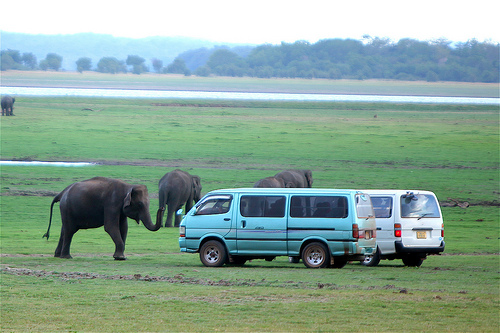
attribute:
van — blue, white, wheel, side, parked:
[153, 112, 454, 276]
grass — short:
[178, 289, 217, 316]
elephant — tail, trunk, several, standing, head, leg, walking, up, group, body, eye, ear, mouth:
[36, 163, 154, 276]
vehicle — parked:
[208, 185, 365, 265]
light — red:
[386, 218, 417, 245]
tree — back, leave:
[163, 20, 451, 136]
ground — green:
[164, 293, 221, 332]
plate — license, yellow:
[409, 226, 436, 245]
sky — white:
[209, 23, 253, 39]